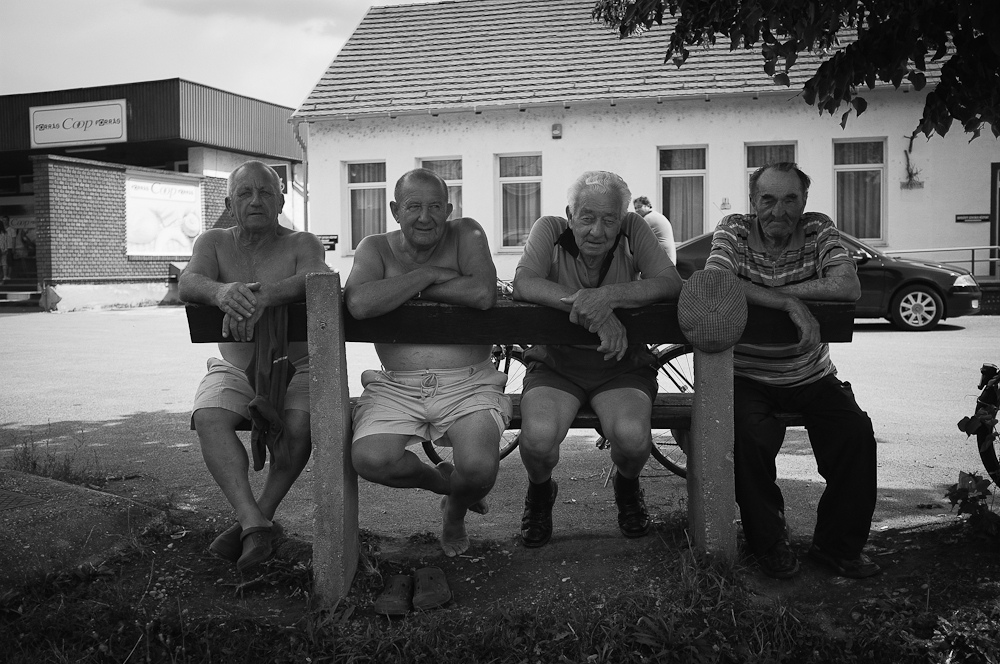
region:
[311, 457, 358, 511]
The woman is holding a large orange.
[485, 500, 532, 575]
The woman is holding a large orange.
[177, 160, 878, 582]
the old men sitting on the bench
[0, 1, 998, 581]
the buildings behind the old men sitting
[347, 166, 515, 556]
the man is wearing shorts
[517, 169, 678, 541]
the man is wearing a shirt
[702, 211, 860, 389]
the shirt is striped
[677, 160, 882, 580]
the hat near the man sitting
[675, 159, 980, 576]
the dark car behind the man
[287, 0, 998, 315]
the windows on the building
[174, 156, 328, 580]
Old topless man wearing shoes.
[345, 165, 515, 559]
Old topless man not wearing his shoes.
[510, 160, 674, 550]
Old man wearing a shirt with a black collar.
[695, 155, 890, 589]
Old man wearing a striped shirt.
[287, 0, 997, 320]
A building with six windows.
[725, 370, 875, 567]
Black pants worn by an old man.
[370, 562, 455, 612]
A pair of old shoes on the ground.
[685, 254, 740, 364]
it is a hat on the post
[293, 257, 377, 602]
a brown pole coming up from under the ground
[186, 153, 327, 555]
old man without a shirt on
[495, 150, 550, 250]
it is a window on the building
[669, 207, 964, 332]
it is a black car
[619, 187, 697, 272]
a man is in the background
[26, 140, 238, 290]
a brick wall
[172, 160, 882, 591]
a group of men sitting on the bench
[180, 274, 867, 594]
the bench the men are sitting on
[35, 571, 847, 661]
the grass next to the bench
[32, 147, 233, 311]
a brick wall seperating the businesses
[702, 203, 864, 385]
the striped shirt the man is wearing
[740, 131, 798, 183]
the window right behind the man's head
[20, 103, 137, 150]
the sign on the building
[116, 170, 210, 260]
a sign on the brick wall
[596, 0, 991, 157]
some branches above the men on the bench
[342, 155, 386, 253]
window on a building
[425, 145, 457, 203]
window on a building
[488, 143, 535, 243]
window on a building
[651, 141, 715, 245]
window on a building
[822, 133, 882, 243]
window on a building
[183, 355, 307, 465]
pair of shorts on a man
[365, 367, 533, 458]
pair of shorts on a man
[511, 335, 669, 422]
pair of shorts on a man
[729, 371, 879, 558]
pair of pants on a man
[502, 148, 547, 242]
A window on a building.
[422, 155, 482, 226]
A window on a building.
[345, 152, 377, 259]
A window on a building.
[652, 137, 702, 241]
A window on a building.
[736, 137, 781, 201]
A window on a building.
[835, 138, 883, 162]
A window on a building.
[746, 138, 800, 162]
A window on a building.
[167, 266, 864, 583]
bench on edge of grass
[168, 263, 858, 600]
bench holding group of men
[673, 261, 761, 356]
cap hanging on back of bench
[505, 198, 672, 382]
man wearing plain shirt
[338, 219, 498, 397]
man wearing no shirt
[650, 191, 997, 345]
parked car is small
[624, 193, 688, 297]
man standing beside car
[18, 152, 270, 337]
brick wall between buildings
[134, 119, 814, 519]
men sitting on bench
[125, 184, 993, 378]
arms resting on rail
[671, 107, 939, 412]
car is behind men